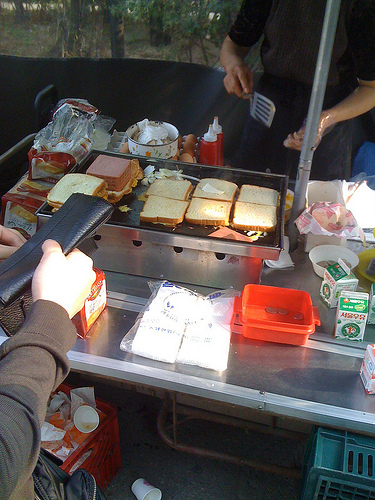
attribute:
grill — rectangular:
[33, 146, 291, 295]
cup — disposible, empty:
[132, 478, 163, 499]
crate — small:
[40, 385, 122, 494]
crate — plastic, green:
[300, 426, 374, 500]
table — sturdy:
[1, 141, 374, 444]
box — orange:
[233, 283, 322, 346]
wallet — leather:
[2, 193, 115, 309]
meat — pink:
[86, 155, 133, 193]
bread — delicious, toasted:
[138, 194, 189, 226]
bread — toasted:
[231, 200, 280, 233]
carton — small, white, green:
[333, 289, 369, 344]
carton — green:
[318, 257, 360, 308]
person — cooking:
[219, 0, 374, 180]